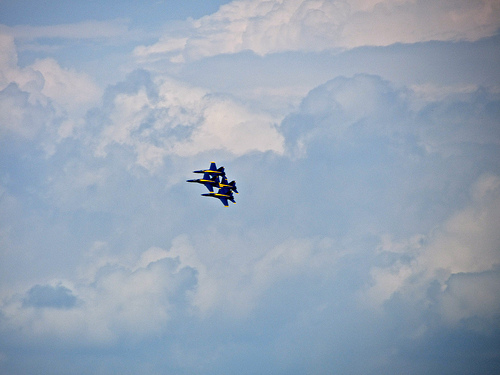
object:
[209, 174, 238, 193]
airplane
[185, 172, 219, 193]
airplane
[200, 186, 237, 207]
airplane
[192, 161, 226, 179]
planes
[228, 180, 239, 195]
tail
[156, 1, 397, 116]
clouds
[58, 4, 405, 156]
sky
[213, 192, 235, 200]
fuselage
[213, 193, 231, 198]
stripe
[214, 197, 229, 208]
wing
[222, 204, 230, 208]
wingtip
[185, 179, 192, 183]
nose